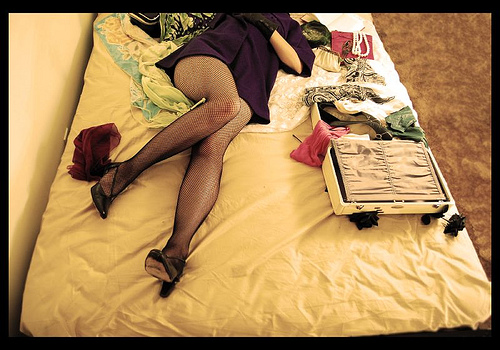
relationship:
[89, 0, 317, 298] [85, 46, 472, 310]
girl in bed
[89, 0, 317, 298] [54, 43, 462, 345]
girl in bed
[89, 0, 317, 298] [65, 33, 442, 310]
girl in bed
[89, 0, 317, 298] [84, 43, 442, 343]
girl in bed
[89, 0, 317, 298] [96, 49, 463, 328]
girl in bed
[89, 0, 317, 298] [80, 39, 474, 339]
girl in bed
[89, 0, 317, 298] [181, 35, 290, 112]
girl in coat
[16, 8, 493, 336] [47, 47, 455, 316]
bed sheet on bed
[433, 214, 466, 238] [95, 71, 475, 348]
flower on bed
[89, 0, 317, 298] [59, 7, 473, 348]
girl on bed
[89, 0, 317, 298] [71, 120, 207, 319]
girl wears heels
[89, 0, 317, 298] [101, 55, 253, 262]
girl wears fishnets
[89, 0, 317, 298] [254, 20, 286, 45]
girl wears gloves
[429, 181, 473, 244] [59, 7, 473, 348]
flower on bed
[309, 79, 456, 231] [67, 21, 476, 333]
luggage on bed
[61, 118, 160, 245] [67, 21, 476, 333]
object on bed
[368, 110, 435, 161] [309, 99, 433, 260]
item in suitcase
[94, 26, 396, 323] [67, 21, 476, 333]
girl on bed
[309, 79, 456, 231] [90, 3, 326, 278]
luggage next to woman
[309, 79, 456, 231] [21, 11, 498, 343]
luggage on bed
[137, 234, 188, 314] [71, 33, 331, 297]
foot on woman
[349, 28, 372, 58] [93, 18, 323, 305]
necklace next to woman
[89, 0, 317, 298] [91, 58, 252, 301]
girl has legs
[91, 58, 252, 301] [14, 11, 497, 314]
legs on bed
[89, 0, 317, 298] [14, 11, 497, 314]
girl on bed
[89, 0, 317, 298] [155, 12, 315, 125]
girl wearing coat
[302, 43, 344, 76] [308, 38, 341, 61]
makeup bag has closure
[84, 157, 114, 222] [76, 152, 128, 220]
shoe on feet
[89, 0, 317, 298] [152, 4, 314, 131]
girl wearing dress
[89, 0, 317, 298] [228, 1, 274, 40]
girl wearing glove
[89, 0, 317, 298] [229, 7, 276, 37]
girl wearing glove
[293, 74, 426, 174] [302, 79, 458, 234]
clothes are in luggage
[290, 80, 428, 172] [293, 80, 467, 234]
clothes are in suitcase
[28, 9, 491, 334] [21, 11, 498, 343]
blanket on bed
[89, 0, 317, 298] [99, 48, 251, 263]
girl wearing hills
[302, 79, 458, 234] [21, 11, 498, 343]
luggage on bed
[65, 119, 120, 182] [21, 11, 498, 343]
object on bed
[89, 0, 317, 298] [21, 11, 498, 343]
girl sleeping in bed